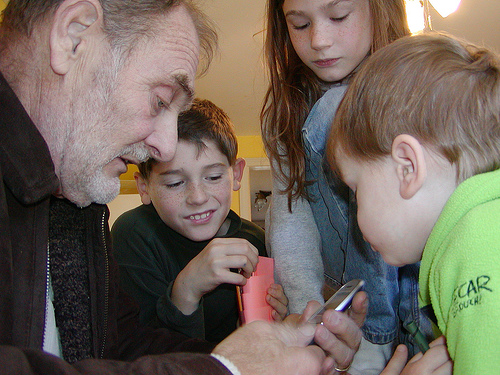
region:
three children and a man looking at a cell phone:
[3, 2, 495, 372]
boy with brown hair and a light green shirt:
[326, 32, 494, 373]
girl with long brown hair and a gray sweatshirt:
[256, 1, 410, 341]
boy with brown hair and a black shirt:
[104, 97, 289, 362]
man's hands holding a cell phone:
[202, 276, 373, 373]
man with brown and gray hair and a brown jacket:
[2, 0, 369, 372]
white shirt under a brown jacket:
[0, 76, 239, 372]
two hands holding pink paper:
[169, 232, 289, 332]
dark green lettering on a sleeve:
[440, 274, 494, 318]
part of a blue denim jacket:
[299, 77, 426, 346]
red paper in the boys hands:
[235, 255, 279, 322]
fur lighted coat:
[47, 205, 92, 355]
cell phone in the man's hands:
[241, 277, 369, 367]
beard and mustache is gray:
[82, 142, 147, 203]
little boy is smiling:
[129, 100, 245, 236]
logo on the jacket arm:
[450, 276, 492, 318]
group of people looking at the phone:
[20, 5, 484, 355]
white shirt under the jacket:
[45, 263, 62, 360]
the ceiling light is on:
[404, 0, 464, 35]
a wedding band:
[334, 359, 350, 373]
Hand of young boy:
[199, 233, 261, 287]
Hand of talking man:
[213, 305, 327, 373]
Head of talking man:
[0, 3, 211, 209]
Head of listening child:
[328, 31, 499, 270]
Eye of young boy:
[160, 174, 185, 193]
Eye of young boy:
[202, 169, 226, 185]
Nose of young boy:
[183, 176, 211, 207]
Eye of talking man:
[144, 79, 179, 115]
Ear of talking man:
[48, 5, 101, 77]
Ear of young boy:
[228, 156, 250, 194]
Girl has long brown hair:
[251, 0, 411, 217]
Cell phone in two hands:
[216, 274, 372, 373]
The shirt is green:
[414, 169, 497, 373]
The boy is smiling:
[133, 96, 246, 242]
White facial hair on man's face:
[50, 73, 153, 212]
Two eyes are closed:
[290, 5, 355, 35]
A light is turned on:
[401, 0, 466, 40]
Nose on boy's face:
[183, 183, 209, 210]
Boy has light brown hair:
[322, 30, 498, 268]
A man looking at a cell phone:
[1, 2, 374, 372]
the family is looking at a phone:
[67, 34, 405, 294]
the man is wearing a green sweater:
[435, 235, 492, 342]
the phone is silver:
[270, 250, 350, 343]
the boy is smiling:
[119, 209, 256, 342]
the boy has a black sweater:
[108, 200, 375, 371]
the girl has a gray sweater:
[252, 120, 342, 338]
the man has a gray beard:
[38, 60, 157, 245]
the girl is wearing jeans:
[307, 164, 414, 365]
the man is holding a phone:
[219, 240, 483, 309]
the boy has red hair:
[402, 55, 465, 142]